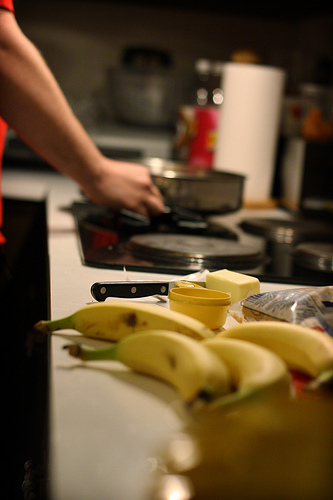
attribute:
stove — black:
[86, 162, 301, 325]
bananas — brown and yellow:
[31, 296, 226, 361]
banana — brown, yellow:
[54, 323, 229, 416]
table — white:
[61, 243, 304, 451]